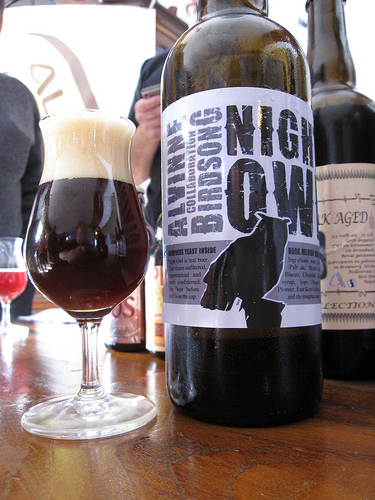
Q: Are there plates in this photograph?
A: No, there are no plates.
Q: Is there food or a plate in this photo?
A: No, there are no plates or food.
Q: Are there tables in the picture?
A: Yes, there is a table.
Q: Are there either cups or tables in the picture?
A: Yes, there is a table.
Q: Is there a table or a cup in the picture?
A: Yes, there is a table.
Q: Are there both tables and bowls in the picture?
A: No, there is a table but no bowls.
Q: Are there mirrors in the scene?
A: No, there are no mirrors.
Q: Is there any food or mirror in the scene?
A: No, there are no mirrors or food.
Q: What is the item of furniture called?
A: The piece of furniture is a table.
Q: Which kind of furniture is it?
A: The piece of furniture is a table.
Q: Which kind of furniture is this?
A: This is a table.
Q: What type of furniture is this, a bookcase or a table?
A: This is a table.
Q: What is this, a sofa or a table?
A: This is a table.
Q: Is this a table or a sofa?
A: This is a table.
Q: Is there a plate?
A: No, there are no plates.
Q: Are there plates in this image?
A: No, there are no plates.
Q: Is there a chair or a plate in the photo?
A: No, there are no plates or chairs.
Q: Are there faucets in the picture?
A: No, there are no faucets.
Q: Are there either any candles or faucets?
A: No, there are no faucets or candles.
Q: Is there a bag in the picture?
A: No, there are no bags.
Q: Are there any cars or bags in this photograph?
A: No, there are no bags or cars.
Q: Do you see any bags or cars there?
A: No, there are no bags or cars.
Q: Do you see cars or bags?
A: No, there are no bags or cars.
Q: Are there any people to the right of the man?
A: Yes, there is a person to the right of the man.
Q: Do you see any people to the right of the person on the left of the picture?
A: Yes, there is a person to the right of the man.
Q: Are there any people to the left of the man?
A: No, the person is to the right of the man.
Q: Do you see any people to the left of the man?
A: No, the person is to the right of the man.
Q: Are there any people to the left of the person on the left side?
A: No, the person is to the right of the man.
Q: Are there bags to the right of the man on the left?
A: No, there is a person to the right of the man.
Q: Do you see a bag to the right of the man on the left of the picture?
A: No, there is a person to the right of the man.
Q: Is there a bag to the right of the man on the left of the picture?
A: No, there is a person to the right of the man.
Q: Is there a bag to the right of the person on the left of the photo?
A: No, there is a person to the right of the man.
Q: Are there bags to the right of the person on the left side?
A: No, there is a person to the right of the man.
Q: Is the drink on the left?
A: Yes, the drink is on the left of the image.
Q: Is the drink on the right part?
A: No, the drink is on the left of the image.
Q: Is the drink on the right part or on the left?
A: The drink is on the left of the image.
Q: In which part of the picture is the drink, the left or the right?
A: The drink is on the left of the image.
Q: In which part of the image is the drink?
A: The drink is on the left of the image.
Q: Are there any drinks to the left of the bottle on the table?
A: Yes, there is a drink to the left of the bottle.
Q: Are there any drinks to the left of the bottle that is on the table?
A: Yes, there is a drink to the left of the bottle.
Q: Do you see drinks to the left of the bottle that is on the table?
A: Yes, there is a drink to the left of the bottle.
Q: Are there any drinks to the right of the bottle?
A: No, the drink is to the left of the bottle.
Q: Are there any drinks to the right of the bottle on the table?
A: No, the drink is to the left of the bottle.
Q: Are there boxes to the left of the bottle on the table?
A: No, there is a drink to the left of the bottle.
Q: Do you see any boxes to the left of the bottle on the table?
A: No, there is a drink to the left of the bottle.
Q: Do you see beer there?
A: Yes, there is beer.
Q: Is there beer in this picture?
A: Yes, there is beer.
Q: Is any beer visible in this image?
A: Yes, there is beer.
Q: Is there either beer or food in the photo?
A: Yes, there is beer.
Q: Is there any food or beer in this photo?
A: Yes, there is beer.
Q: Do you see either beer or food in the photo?
A: Yes, there is beer.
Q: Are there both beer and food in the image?
A: No, there is beer but no food.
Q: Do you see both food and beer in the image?
A: No, there is beer but no food.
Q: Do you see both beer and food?
A: No, there is beer but no food.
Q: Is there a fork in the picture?
A: No, there are no forks.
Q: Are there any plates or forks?
A: No, there are no forks or plates.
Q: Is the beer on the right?
A: No, the beer is on the left of the image.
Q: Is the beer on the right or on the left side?
A: The beer is on the left of the image.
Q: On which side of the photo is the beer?
A: The beer is on the left of the image.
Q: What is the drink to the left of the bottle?
A: The drink is beer.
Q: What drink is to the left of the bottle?
A: The drink is beer.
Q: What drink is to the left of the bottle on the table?
A: The drink is beer.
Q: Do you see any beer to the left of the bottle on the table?
A: Yes, there is beer to the left of the bottle.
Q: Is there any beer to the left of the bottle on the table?
A: Yes, there is beer to the left of the bottle.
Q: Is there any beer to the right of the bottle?
A: No, the beer is to the left of the bottle.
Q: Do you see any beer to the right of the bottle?
A: No, the beer is to the left of the bottle.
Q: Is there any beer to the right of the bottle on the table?
A: No, the beer is to the left of the bottle.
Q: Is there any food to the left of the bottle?
A: No, there is beer to the left of the bottle.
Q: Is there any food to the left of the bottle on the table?
A: No, there is beer to the left of the bottle.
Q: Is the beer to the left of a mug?
A: No, the beer is to the left of a bottle.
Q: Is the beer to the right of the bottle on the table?
A: No, the beer is to the left of the bottle.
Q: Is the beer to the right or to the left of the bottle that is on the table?
A: The beer is to the left of the bottle.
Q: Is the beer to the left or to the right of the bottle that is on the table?
A: The beer is to the left of the bottle.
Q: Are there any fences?
A: No, there are no fences.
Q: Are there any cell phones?
A: Yes, there is a cell phone.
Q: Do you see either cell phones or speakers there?
A: Yes, there is a cell phone.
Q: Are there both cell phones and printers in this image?
A: No, there is a cell phone but no printers.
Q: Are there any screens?
A: No, there are no screens.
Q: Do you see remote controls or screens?
A: No, there are no screens or remote controls.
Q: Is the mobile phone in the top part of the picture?
A: Yes, the mobile phone is in the top of the image.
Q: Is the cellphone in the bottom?
A: No, the cellphone is in the top of the image.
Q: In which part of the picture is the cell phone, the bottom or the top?
A: The cell phone is in the top of the image.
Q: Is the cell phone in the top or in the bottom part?
A: The cell phone is in the top of the image.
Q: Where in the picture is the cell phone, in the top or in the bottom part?
A: The cell phone is in the top of the image.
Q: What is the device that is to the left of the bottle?
A: The device is a cell phone.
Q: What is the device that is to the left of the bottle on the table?
A: The device is a cell phone.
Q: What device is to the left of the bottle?
A: The device is a cell phone.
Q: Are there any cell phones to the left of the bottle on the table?
A: Yes, there is a cell phone to the left of the bottle.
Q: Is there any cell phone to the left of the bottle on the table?
A: Yes, there is a cell phone to the left of the bottle.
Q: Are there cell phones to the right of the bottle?
A: No, the cell phone is to the left of the bottle.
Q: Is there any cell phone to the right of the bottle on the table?
A: No, the cell phone is to the left of the bottle.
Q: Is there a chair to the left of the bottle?
A: No, there is a cell phone to the left of the bottle.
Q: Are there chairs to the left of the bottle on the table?
A: No, there is a cell phone to the left of the bottle.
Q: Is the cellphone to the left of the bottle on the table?
A: Yes, the cellphone is to the left of the bottle.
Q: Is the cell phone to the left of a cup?
A: No, the cell phone is to the left of the bottle.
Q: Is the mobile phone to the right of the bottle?
A: No, the mobile phone is to the left of the bottle.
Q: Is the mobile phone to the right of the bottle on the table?
A: No, the mobile phone is to the left of the bottle.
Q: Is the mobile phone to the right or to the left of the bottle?
A: The mobile phone is to the left of the bottle.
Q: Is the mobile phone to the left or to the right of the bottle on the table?
A: The mobile phone is to the left of the bottle.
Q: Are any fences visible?
A: No, there are no fences.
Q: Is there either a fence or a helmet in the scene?
A: No, there are no fences or helmets.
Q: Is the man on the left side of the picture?
A: Yes, the man is on the left of the image.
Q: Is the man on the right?
A: No, the man is on the left of the image.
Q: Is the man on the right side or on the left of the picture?
A: The man is on the left of the image.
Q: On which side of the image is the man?
A: The man is on the left of the image.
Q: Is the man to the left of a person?
A: Yes, the man is to the left of a person.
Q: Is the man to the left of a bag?
A: No, the man is to the left of a person.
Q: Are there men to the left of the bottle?
A: Yes, there is a man to the left of the bottle.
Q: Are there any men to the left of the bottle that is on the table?
A: Yes, there is a man to the left of the bottle.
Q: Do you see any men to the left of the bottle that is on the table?
A: Yes, there is a man to the left of the bottle.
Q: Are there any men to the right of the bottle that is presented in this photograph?
A: No, the man is to the left of the bottle.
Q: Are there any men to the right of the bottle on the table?
A: No, the man is to the left of the bottle.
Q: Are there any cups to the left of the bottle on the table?
A: No, there is a man to the left of the bottle.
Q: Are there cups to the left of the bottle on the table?
A: No, there is a man to the left of the bottle.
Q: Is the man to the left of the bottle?
A: Yes, the man is to the left of the bottle.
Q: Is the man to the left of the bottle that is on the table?
A: Yes, the man is to the left of the bottle.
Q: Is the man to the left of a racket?
A: No, the man is to the left of the bottle.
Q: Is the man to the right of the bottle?
A: No, the man is to the left of the bottle.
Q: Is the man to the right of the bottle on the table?
A: No, the man is to the left of the bottle.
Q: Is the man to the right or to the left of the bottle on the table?
A: The man is to the left of the bottle.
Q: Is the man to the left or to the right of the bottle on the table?
A: The man is to the left of the bottle.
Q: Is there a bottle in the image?
A: Yes, there is a bottle.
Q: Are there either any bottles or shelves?
A: Yes, there is a bottle.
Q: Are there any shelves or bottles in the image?
A: Yes, there is a bottle.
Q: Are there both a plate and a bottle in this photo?
A: No, there is a bottle but no plates.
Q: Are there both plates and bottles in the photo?
A: No, there is a bottle but no plates.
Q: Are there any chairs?
A: No, there are no chairs.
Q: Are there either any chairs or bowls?
A: No, there are no chairs or bowls.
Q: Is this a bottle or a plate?
A: This is a bottle.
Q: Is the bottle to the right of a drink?
A: Yes, the bottle is to the right of a drink.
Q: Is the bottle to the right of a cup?
A: No, the bottle is to the right of a drink.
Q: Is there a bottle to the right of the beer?
A: Yes, there is a bottle to the right of the beer.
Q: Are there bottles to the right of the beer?
A: Yes, there is a bottle to the right of the beer.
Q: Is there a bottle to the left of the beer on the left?
A: No, the bottle is to the right of the beer.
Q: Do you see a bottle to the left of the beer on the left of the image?
A: No, the bottle is to the right of the beer.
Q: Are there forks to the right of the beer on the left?
A: No, there is a bottle to the right of the beer.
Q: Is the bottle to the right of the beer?
A: Yes, the bottle is to the right of the beer.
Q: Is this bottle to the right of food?
A: No, the bottle is to the right of the beer.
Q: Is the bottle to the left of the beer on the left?
A: No, the bottle is to the right of the beer.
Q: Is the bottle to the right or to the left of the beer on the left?
A: The bottle is to the right of the beer.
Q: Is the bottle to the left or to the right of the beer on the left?
A: The bottle is to the right of the beer.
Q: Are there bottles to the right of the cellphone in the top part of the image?
A: Yes, there is a bottle to the right of the cellphone.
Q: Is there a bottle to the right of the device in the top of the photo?
A: Yes, there is a bottle to the right of the cellphone.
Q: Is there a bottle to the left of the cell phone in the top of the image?
A: No, the bottle is to the right of the cellphone.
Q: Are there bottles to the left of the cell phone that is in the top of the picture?
A: No, the bottle is to the right of the cellphone.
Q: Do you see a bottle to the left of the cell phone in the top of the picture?
A: No, the bottle is to the right of the cellphone.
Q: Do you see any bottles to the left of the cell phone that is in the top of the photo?
A: No, the bottle is to the right of the cellphone.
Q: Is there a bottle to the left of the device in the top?
A: No, the bottle is to the right of the cellphone.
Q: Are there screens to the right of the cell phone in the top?
A: No, there is a bottle to the right of the cell phone.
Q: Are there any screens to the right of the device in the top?
A: No, there is a bottle to the right of the cell phone.